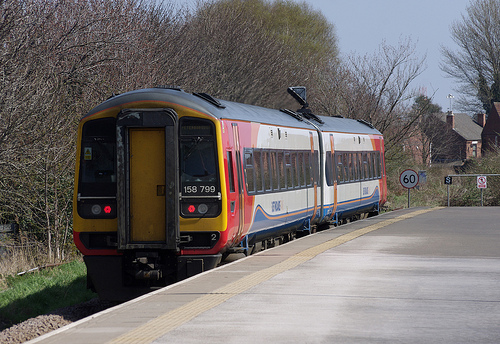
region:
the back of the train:
[68, 102, 243, 251]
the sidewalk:
[258, 289, 368, 341]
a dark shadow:
[53, 283, 92, 305]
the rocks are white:
[13, 316, 39, 337]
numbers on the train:
[180, 184, 227, 194]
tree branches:
[178, 30, 259, 75]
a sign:
[399, 167, 416, 184]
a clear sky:
[384, 12, 429, 34]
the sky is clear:
[367, 5, 406, 40]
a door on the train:
[129, 134, 164, 239]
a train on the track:
[87, 44, 485, 244]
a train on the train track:
[29, 30, 312, 337]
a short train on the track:
[103, 80, 350, 318]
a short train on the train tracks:
[93, 36, 295, 325]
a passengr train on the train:
[71, 43, 403, 337]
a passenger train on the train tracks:
[46, 56, 383, 319]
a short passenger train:
[57, 53, 479, 330]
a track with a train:
[61, 58, 467, 332]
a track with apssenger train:
[97, 54, 352, 329]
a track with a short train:
[40, 107, 277, 290]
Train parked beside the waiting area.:
[72, 43, 383, 271]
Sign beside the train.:
[396, 154, 423, 204]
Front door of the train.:
[121, 110, 173, 252]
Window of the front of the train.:
[175, 113, 225, 195]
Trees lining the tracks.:
[12, 10, 337, 78]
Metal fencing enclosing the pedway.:
[442, 168, 496, 206]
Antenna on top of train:
[289, 79, 320, 128]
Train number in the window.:
[180, 175, 225, 200]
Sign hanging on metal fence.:
[474, 174, 489, 189]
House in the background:
[424, 89, 489, 173]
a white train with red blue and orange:
[64, 60, 423, 262]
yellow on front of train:
[65, 95, 227, 250]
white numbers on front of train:
[182, 179, 234, 201]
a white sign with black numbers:
[395, 171, 427, 203]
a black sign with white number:
[440, 170, 455, 190]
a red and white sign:
[470, 169, 496, 194]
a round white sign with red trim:
[394, 164, 431, 197]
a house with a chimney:
[405, 87, 495, 179]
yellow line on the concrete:
[116, 187, 471, 333]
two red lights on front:
[95, 201, 197, 210]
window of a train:
[86, 119, 140, 196]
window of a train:
[172, 122, 239, 203]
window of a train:
[242, 145, 267, 193]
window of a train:
[266, 156, 297, 198]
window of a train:
[287, 156, 325, 203]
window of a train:
[325, 142, 347, 180]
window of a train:
[336, 146, 358, 183]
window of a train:
[343, 145, 373, 190]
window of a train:
[359, 143, 386, 187]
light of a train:
[179, 196, 217, 228]